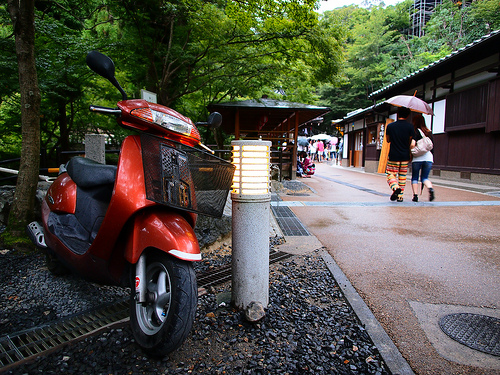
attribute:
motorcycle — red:
[24, 46, 222, 353]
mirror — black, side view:
[77, 41, 126, 91]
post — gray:
[220, 128, 281, 337]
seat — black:
[64, 147, 129, 196]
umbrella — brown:
[387, 85, 444, 132]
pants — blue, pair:
[406, 154, 437, 186]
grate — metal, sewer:
[435, 300, 498, 360]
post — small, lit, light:
[224, 129, 293, 327]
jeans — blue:
[406, 158, 442, 189]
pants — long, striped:
[383, 155, 412, 199]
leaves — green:
[259, 7, 345, 98]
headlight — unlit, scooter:
[136, 108, 203, 138]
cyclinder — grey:
[229, 194, 274, 319]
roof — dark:
[213, 95, 325, 124]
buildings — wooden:
[340, 26, 498, 171]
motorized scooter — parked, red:
[27, 47, 235, 358]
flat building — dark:
[405, 0, 483, 45]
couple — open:
[381, 81, 443, 216]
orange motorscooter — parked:
[24, 48, 211, 361]